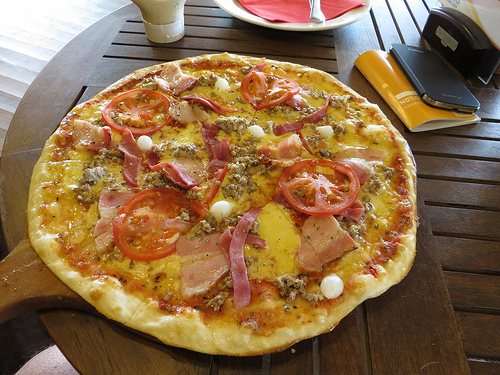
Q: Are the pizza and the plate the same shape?
A: Yes, both the pizza and the plate are round.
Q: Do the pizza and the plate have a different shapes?
A: No, both the pizza and the plate are round.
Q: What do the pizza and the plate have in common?
A: The shape, both the pizza and the plate are round.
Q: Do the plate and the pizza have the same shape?
A: Yes, both the plate and the pizza are round.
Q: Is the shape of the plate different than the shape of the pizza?
A: No, both the plate and the pizza are round.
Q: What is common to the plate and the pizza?
A: The shape, both the plate and the pizza are round.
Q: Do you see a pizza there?
A: Yes, there is a pizza.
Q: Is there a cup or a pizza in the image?
A: Yes, there is a pizza.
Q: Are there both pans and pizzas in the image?
A: No, there is a pizza but no pans.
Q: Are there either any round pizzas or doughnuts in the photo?
A: Yes, there is a round pizza.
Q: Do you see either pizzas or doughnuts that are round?
A: Yes, the pizza is round.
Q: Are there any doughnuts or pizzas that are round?
A: Yes, the pizza is round.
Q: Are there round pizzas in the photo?
A: Yes, there is a round pizza.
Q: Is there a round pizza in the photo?
A: Yes, there is a round pizza.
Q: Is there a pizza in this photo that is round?
A: Yes, there is a pizza that is round.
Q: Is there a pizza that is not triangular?
A: Yes, there is a round pizza.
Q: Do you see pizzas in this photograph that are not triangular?
A: Yes, there is a round pizza.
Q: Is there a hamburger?
A: No, there are no hamburgers.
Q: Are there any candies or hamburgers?
A: No, there are no hamburgers or candies.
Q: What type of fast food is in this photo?
A: The fast food is a pizza.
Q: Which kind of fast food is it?
A: The food is a pizza.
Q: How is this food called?
A: This is a pizza.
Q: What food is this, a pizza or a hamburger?
A: This is a pizza.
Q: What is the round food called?
A: The food is a pizza.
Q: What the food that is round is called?
A: The food is a pizza.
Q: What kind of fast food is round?
A: The fast food is a pizza.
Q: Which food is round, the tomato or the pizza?
A: The pizza is round.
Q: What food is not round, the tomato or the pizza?
A: The tomato is not round.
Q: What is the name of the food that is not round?
A: The food is a tomato.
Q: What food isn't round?
A: The food is a tomato.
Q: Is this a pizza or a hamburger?
A: This is a pizza.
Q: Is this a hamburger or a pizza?
A: This is a pizza.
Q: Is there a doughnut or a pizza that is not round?
A: No, there is a pizza but it is round.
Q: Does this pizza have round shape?
A: Yes, the pizza is round.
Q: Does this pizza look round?
A: Yes, the pizza is round.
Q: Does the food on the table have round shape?
A: Yes, the pizza is round.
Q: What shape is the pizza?
A: The pizza is round.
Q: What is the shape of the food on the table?
A: The pizza is round.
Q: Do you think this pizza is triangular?
A: No, the pizza is round.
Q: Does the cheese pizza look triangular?
A: No, the pizza is round.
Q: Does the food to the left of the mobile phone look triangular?
A: No, the pizza is round.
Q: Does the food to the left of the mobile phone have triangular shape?
A: No, the pizza is round.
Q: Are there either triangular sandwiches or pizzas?
A: No, there is a pizza but it is round.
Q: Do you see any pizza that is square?
A: No, there is a pizza but it is round.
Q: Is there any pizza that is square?
A: No, there is a pizza but it is round.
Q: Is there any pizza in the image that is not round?
A: No, there is a pizza but it is round.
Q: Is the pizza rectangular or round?
A: The pizza is round.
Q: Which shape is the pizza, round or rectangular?
A: The pizza is round.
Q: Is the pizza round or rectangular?
A: The pizza is round.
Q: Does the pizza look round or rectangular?
A: The pizza is round.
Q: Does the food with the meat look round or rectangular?
A: The pizza is round.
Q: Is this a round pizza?
A: Yes, this is a round pizza.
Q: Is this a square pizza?
A: No, this is a round pizza.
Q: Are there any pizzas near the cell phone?
A: Yes, there is a pizza near the cell phone.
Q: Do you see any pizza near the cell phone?
A: Yes, there is a pizza near the cell phone.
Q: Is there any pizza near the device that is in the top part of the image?
A: Yes, there is a pizza near the cell phone.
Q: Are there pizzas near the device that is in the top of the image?
A: Yes, there is a pizza near the cell phone.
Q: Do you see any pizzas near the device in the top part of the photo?
A: Yes, there is a pizza near the cell phone.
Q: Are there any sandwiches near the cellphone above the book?
A: No, there is a pizza near the cellphone.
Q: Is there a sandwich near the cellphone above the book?
A: No, there is a pizza near the cellphone.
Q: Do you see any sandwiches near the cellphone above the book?
A: No, there is a pizza near the cellphone.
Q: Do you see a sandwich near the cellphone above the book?
A: No, there is a pizza near the cellphone.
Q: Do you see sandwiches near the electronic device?
A: No, there is a pizza near the cellphone.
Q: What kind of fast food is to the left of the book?
A: The food is a pizza.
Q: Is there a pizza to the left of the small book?
A: Yes, there is a pizza to the left of the book.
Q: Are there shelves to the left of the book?
A: No, there is a pizza to the left of the book.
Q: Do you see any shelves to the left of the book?
A: No, there is a pizza to the left of the book.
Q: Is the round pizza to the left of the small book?
A: Yes, the pizza is to the left of the book.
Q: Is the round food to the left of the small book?
A: Yes, the pizza is to the left of the book.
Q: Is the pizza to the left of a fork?
A: No, the pizza is to the left of the book.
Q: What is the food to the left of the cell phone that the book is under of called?
A: The food is a pizza.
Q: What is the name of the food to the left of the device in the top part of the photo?
A: The food is a pizza.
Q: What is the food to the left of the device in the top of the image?
A: The food is a pizza.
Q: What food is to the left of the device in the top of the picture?
A: The food is a pizza.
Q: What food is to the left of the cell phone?
A: The food is a pizza.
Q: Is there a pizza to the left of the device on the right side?
A: Yes, there is a pizza to the left of the cellphone.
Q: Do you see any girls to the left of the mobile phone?
A: No, there is a pizza to the left of the mobile phone.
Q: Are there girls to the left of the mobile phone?
A: No, there is a pizza to the left of the mobile phone.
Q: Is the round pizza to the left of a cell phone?
A: Yes, the pizza is to the left of a cell phone.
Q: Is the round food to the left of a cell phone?
A: Yes, the pizza is to the left of a cell phone.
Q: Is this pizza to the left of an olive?
A: No, the pizza is to the left of a cell phone.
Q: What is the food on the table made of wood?
A: The food is a pizza.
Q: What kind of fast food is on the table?
A: The food is a pizza.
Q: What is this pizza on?
A: The pizza is on the table.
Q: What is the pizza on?
A: The pizza is on the table.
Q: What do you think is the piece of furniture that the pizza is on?
A: The piece of furniture is a table.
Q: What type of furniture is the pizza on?
A: The pizza is on the table.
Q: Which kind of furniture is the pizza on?
A: The pizza is on the table.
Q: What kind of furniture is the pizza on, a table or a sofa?
A: The pizza is on a table.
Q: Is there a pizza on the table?
A: Yes, there is a pizza on the table.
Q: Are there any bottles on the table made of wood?
A: No, there is a pizza on the table.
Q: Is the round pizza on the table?
A: Yes, the pizza is on the table.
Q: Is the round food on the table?
A: Yes, the pizza is on the table.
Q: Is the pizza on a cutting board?
A: No, the pizza is on the table.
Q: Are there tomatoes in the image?
A: Yes, there is a tomato.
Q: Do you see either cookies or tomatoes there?
A: Yes, there is a tomato.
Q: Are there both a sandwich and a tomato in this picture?
A: No, there is a tomato but no sandwiches.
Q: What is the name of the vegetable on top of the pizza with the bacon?
A: The vegetable is a tomato.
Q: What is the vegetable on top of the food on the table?
A: The vegetable is a tomato.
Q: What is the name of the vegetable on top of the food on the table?
A: The vegetable is a tomato.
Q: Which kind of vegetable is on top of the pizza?
A: The vegetable is a tomato.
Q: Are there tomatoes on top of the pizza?
A: Yes, there is a tomato on top of the pizza.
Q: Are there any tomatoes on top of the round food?
A: Yes, there is a tomato on top of the pizza.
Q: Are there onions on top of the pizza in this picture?
A: No, there is a tomato on top of the pizza.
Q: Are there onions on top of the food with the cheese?
A: No, there is a tomato on top of the pizza.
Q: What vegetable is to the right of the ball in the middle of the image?
A: The vegetable is a tomato.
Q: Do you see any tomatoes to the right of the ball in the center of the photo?
A: Yes, there is a tomato to the right of the ball.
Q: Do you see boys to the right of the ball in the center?
A: No, there is a tomato to the right of the ball.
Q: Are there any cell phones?
A: Yes, there is a cell phone.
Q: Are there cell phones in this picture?
A: Yes, there is a cell phone.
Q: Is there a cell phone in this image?
A: Yes, there is a cell phone.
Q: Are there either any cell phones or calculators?
A: Yes, there is a cell phone.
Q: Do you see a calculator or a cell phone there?
A: Yes, there is a cell phone.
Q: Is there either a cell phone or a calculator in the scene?
A: Yes, there is a cell phone.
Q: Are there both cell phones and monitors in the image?
A: No, there is a cell phone but no monitors.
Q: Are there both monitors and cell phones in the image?
A: No, there is a cell phone but no monitors.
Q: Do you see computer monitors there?
A: No, there are no computer monitors.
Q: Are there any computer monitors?
A: No, there are no computer monitors.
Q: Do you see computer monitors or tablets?
A: No, there are no computer monitors or tablets.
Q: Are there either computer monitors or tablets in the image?
A: No, there are no computer monitors or tablets.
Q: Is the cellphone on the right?
A: Yes, the cellphone is on the right of the image.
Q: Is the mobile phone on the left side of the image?
A: No, the mobile phone is on the right of the image.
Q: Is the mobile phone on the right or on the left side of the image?
A: The mobile phone is on the right of the image.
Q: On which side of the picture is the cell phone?
A: The cell phone is on the right of the image.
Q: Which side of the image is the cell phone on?
A: The cell phone is on the right of the image.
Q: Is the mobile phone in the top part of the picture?
A: Yes, the mobile phone is in the top of the image.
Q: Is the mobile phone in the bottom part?
A: No, the mobile phone is in the top of the image.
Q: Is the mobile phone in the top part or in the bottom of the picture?
A: The mobile phone is in the top of the image.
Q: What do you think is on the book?
A: The cell phone is on the book.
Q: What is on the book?
A: The cell phone is on the book.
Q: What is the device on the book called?
A: The device is a cell phone.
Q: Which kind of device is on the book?
A: The device is a cell phone.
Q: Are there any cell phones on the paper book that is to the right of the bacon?
A: Yes, there is a cell phone on the book.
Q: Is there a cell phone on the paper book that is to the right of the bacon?
A: Yes, there is a cell phone on the book.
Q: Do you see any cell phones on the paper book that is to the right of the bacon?
A: Yes, there is a cell phone on the book.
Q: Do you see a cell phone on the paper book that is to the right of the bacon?
A: Yes, there is a cell phone on the book.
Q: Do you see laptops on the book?
A: No, there is a cell phone on the book.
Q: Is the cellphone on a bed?
A: No, the cellphone is on the book.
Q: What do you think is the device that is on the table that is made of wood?
A: The device is a cell phone.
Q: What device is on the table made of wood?
A: The device is a cell phone.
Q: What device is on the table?
A: The device is a cell phone.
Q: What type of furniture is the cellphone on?
A: The cellphone is on the table.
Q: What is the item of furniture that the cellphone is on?
A: The piece of furniture is a table.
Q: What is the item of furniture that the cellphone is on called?
A: The piece of furniture is a table.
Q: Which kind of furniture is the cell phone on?
A: The cellphone is on the table.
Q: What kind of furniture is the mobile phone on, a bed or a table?
A: The mobile phone is on a table.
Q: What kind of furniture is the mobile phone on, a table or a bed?
A: The mobile phone is on a table.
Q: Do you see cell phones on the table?
A: Yes, there is a cell phone on the table.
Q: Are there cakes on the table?
A: No, there is a cell phone on the table.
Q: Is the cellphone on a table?
A: Yes, the cellphone is on a table.